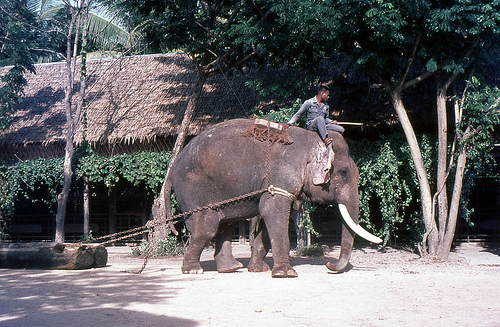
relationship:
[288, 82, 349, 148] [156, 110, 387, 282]
man riding elephant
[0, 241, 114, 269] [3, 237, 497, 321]
logs dragged on ground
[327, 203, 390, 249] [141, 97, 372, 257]
tusk on an elephant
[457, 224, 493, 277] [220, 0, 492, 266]
path between trees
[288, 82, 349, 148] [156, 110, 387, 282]
man sitting on elephant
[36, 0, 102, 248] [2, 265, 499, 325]
palm tree beside road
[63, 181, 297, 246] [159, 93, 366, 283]
chain fixed to elephant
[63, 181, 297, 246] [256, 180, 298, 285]
chain fixed to leg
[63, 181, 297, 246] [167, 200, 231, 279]
chain fixed to leg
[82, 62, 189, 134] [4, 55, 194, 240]
roof of building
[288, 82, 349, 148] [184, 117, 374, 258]
man on elephant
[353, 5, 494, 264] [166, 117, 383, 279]
tree behind elephant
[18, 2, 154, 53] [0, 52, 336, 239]
palm tree behind building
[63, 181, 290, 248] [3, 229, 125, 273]
chain connecting logs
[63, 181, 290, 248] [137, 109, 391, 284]
chain connecting elephant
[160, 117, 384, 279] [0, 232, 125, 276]
elephant pulling logs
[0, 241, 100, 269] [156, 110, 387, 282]
logs chained to elephant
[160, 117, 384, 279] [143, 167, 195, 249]
elephant has tail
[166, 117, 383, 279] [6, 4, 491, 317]
elephant walking in park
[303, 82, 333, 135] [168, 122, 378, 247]
man on elephant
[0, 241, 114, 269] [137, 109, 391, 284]
logs on elephant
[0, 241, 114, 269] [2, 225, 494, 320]
logs on ground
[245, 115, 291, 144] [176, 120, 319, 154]
saddle on back